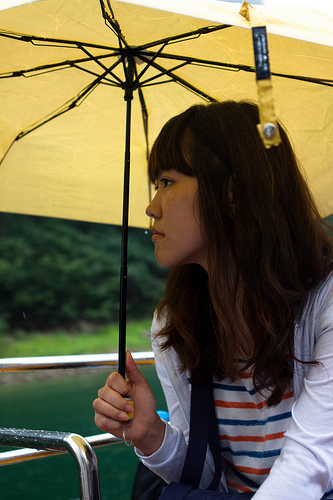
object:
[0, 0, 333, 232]
umbrella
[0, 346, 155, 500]
railing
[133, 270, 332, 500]
shirt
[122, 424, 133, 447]
ring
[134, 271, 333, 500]
jacket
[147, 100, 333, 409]
hair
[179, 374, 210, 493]
strap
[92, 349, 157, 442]
hand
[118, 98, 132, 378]
pole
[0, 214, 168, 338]
bush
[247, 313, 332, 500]
sleeve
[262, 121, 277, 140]
button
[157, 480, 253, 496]
bag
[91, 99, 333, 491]
girl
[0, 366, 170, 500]
lake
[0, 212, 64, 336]
trees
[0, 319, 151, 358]
grass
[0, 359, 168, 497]
water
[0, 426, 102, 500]
rail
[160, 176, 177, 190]
eye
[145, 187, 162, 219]
nose